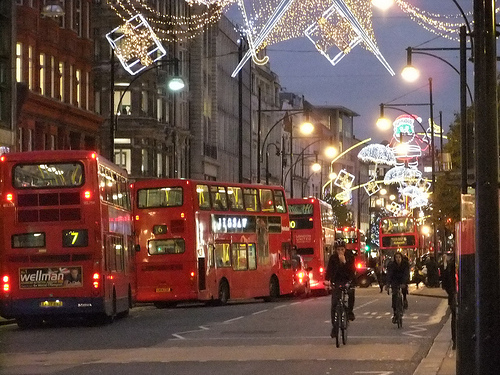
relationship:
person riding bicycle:
[323, 239, 359, 339] [323, 281, 354, 350]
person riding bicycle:
[386, 250, 409, 322] [385, 284, 410, 329]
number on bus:
[68, 232, 79, 246] [0, 147, 135, 324]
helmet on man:
[333, 239, 347, 248] [323, 239, 359, 339]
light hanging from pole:
[400, 46, 421, 87] [459, 26, 469, 199]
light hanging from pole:
[377, 103, 391, 133] [428, 76, 436, 198]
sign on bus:
[20, 267, 85, 288] [0, 147, 135, 324]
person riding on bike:
[323, 239, 359, 339] [323, 281, 354, 350]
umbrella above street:
[356, 141, 399, 182] [3, 285, 451, 375]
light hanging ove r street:
[400, 46, 421, 87] [3, 285, 451, 375]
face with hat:
[393, 122, 416, 141] [391, 112, 423, 128]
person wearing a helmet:
[323, 239, 359, 339] [333, 239, 347, 248]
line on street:
[223, 314, 245, 324] [3, 285, 451, 375]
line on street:
[254, 308, 270, 318] [3, 285, 451, 375]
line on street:
[274, 304, 285, 313] [3, 285, 451, 375]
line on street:
[289, 300, 305, 308] [3, 285, 451, 375]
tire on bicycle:
[336, 306, 341, 348] [323, 281, 354, 350]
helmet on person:
[333, 239, 347, 248] [323, 239, 359, 339]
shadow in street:
[0, 304, 244, 352] [3, 285, 451, 375]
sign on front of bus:
[382, 234, 415, 250] [380, 215, 438, 273]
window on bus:
[231, 240, 257, 272] [128, 178, 295, 304]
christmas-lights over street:
[100, 4, 474, 79] [3, 285, 451, 375]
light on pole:
[400, 46, 421, 87] [459, 26, 469, 199]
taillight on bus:
[190, 269, 196, 290] [128, 178, 295, 304]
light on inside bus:
[197, 186, 205, 195] [128, 178, 295, 304]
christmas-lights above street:
[100, 4, 474, 79] [3, 285, 451, 375]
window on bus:
[215, 239, 232, 268] [128, 178, 295, 304]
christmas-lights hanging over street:
[100, 4, 474, 79] [3, 285, 451, 375]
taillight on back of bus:
[319, 262, 325, 280] [287, 194, 336, 292]